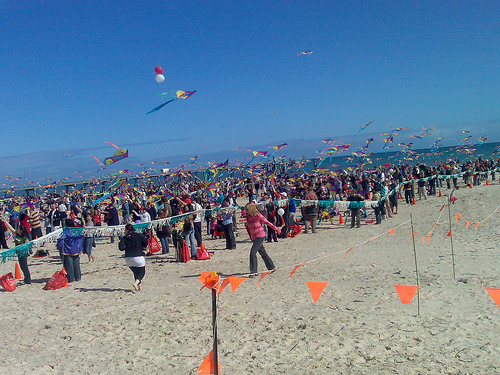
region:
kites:
[150, 61, 192, 116]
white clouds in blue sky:
[357, 29, 389, 63]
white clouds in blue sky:
[324, 66, 388, 107]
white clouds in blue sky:
[437, 49, 498, 84]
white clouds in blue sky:
[297, 65, 357, 117]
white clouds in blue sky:
[245, 31, 300, 129]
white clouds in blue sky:
[45, 23, 90, 87]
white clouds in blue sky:
[10, 48, 37, 85]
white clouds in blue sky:
[25, 55, 75, 116]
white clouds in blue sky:
[54, 82, 112, 140]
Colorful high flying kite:
[147, 63, 173, 85]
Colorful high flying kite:
[148, 84, 198, 117]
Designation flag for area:
[299, 274, 335, 307]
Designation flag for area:
[387, 279, 428, 312]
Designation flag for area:
[37, 268, 70, 294]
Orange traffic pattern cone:
[11, 264, 23, 281]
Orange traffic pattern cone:
[179, 240, 194, 267]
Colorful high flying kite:
[85, 146, 136, 171]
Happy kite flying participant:
[233, 204, 283, 280]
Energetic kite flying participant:
[114, 221, 155, 293]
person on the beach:
[234, 200, 275, 275]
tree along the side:
[111, 214, 147, 290]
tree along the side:
[58, 223, 92, 291]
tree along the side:
[335, 188, 359, 231]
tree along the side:
[344, 186, 366, 228]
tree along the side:
[79, 210, 102, 260]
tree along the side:
[10, 225, 43, 290]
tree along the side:
[87, 198, 118, 241]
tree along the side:
[149, 211, 171, 244]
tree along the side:
[456, 165, 476, 190]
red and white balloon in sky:
[151, 52, 174, 90]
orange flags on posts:
[178, 263, 495, 371]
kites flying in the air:
[61, 87, 493, 165]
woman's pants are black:
[120, 260, 162, 292]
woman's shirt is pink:
[235, 206, 275, 241]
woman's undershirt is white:
[120, 248, 148, 268]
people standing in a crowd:
[0, 153, 498, 283]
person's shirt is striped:
[22, 210, 45, 227]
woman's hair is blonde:
[242, 196, 265, 221]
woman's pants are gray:
[244, 228, 274, 280]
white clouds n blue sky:
[11, 6, 69, 48]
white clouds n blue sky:
[37, 46, 72, 80]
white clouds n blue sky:
[27, 83, 59, 105]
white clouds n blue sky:
[317, 53, 365, 87]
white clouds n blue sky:
[261, 16, 312, 61]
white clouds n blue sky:
[388, 36, 449, 90]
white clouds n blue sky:
[247, 29, 302, 93]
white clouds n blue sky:
[22, 106, 113, 157]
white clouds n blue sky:
[85, 42, 119, 73]